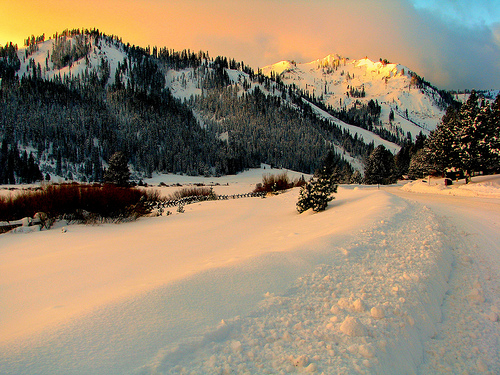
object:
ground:
[0, 174, 500, 373]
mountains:
[0, 23, 406, 189]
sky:
[0, 1, 499, 97]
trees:
[96, 149, 134, 189]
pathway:
[374, 176, 500, 373]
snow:
[256, 53, 454, 183]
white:
[370, 83, 387, 94]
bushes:
[0, 178, 163, 221]